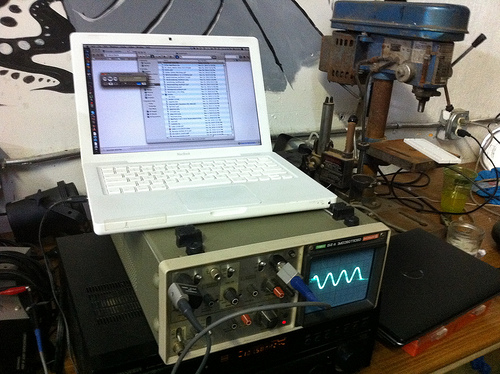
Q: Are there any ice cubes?
A: No, there are no ice cubes.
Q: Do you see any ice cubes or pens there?
A: No, there are no ice cubes or pens.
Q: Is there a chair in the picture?
A: No, there are no chairs.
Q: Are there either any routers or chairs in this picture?
A: No, there are no chairs or routers.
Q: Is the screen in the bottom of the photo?
A: Yes, the screen is in the bottom of the image.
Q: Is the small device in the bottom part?
A: Yes, the screen is in the bottom of the image.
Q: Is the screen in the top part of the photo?
A: No, the screen is in the bottom of the image.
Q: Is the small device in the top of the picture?
A: No, the screen is in the bottom of the image.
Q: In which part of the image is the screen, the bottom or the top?
A: The screen is in the bottom of the image.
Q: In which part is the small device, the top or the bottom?
A: The screen is in the bottom of the image.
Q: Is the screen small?
A: Yes, the screen is small.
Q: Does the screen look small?
A: Yes, the screen is small.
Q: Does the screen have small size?
A: Yes, the screen is small.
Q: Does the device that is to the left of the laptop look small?
A: Yes, the screen is small.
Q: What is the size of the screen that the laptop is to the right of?
A: The screen is small.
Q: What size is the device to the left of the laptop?
A: The screen is small.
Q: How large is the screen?
A: The screen is small.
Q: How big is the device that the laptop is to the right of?
A: The screen is small.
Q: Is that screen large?
A: No, the screen is small.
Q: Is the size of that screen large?
A: No, the screen is small.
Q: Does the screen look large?
A: No, the screen is small.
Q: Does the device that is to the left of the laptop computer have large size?
A: No, the screen is small.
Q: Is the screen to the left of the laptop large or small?
A: The screen is small.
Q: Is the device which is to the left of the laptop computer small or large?
A: The screen is small.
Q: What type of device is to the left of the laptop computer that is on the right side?
A: The device is a screen.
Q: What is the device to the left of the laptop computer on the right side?
A: The device is a screen.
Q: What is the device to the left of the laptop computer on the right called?
A: The device is a screen.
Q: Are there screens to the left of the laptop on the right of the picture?
A: Yes, there is a screen to the left of the laptop computer.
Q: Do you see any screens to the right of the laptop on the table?
A: No, the screen is to the left of the laptop.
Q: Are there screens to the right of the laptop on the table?
A: No, the screen is to the left of the laptop.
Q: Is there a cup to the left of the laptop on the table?
A: No, there is a screen to the left of the laptop.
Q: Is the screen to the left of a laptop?
A: Yes, the screen is to the left of a laptop.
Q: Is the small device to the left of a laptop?
A: Yes, the screen is to the left of a laptop.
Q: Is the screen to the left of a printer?
A: No, the screen is to the left of a laptop.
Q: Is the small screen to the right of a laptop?
A: No, the screen is to the left of a laptop.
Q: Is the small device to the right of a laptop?
A: No, the screen is to the left of a laptop.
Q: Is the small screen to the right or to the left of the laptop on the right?
A: The screen is to the left of the laptop computer.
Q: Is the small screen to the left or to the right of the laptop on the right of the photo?
A: The screen is to the left of the laptop computer.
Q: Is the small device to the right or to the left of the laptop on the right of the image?
A: The screen is to the left of the laptop computer.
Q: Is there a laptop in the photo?
A: Yes, there is a laptop.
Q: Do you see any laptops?
A: Yes, there is a laptop.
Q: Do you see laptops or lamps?
A: Yes, there is a laptop.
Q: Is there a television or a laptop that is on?
A: Yes, the laptop is on.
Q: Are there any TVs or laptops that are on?
A: Yes, the laptop is on.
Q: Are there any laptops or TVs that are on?
A: Yes, the laptop is on.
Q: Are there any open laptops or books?
A: Yes, there is an open laptop.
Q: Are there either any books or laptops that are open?
A: Yes, the laptop is open.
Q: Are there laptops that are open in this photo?
A: Yes, there is an open laptop.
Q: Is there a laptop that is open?
A: Yes, there is a laptop that is open.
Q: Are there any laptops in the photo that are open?
A: Yes, there is a laptop that is open.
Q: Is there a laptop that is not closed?
A: Yes, there is a open laptop.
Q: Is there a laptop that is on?
A: Yes, there is a laptop that is on.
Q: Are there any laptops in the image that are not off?
A: Yes, there is a laptop that is on.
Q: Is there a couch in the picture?
A: No, there are no couches.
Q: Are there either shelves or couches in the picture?
A: No, there are no couches or shelves.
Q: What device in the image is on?
A: The device is a laptop.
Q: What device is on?
A: The device is a laptop.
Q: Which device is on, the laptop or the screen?
A: The laptop is on.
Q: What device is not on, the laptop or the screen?
A: The screen is not on.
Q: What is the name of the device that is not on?
A: The device is a screen.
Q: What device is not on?
A: The device is a screen.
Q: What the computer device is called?
A: The device is a laptop.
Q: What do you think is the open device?
A: The device is a laptop.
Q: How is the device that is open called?
A: The device is a laptop.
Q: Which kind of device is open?
A: The device is a laptop.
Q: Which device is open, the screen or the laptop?
A: The laptop is open.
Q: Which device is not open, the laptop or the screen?
A: The screen is not open.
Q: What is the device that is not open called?
A: The device is a screen.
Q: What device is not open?
A: The device is a screen.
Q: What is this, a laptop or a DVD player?
A: This is a laptop.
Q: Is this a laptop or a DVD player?
A: This is a laptop.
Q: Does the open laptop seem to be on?
A: Yes, the laptop is on.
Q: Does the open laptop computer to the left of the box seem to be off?
A: No, the laptop is on.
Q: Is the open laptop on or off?
A: The laptop computer is on.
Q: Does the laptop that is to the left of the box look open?
A: Yes, the laptop is open.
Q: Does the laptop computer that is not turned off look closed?
A: No, the laptop is open.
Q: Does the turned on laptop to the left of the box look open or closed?
A: The laptop computer is open.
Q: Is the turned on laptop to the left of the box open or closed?
A: The laptop computer is open.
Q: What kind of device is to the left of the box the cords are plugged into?
A: The device is a laptop.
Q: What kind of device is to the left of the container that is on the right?
A: The device is a laptop.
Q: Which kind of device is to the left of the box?
A: The device is a laptop.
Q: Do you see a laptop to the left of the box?
A: Yes, there is a laptop to the left of the box.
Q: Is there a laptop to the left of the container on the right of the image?
A: Yes, there is a laptop to the left of the box.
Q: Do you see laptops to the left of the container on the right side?
A: Yes, there is a laptop to the left of the box.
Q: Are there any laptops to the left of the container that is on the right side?
A: Yes, there is a laptop to the left of the box.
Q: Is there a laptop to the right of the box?
A: No, the laptop is to the left of the box.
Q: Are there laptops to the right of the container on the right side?
A: No, the laptop is to the left of the box.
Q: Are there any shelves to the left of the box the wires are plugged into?
A: No, there is a laptop to the left of the box.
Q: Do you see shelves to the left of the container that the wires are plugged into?
A: No, there is a laptop to the left of the box.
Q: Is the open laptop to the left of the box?
A: Yes, the laptop computer is to the left of the box.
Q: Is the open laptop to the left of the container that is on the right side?
A: Yes, the laptop computer is to the left of the box.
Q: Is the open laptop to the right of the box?
A: No, the laptop is to the left of the box.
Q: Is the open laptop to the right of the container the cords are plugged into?
A: No, the laptop is to the left of the box.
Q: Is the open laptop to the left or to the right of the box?
A: The laptop is to the left of the box.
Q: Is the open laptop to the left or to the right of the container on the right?
A: The laptop is to the left of the box.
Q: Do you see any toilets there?
A: No, there are no toilets.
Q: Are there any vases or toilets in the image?
A: No, there are no toilets or vases.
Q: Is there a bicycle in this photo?
A: No, there are no bicycles.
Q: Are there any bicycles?
A: No, there are no bicycles.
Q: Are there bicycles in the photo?
A: No, there are no bicycles.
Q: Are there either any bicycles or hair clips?
A: No, there are no bicycles or hair clips.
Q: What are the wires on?
A: The wires are on the table.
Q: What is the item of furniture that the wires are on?
A: The piece of furniture is a table.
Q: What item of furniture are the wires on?
A: The wires are on the table.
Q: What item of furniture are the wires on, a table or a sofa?
A: The wires are on a table.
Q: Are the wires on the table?
A: Yes, the wires are on the table.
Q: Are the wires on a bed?
A: No, the wires are on the table.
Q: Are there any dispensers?
A: No, there are no dispensers.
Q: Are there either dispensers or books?
A: No, there are no dispensers or books.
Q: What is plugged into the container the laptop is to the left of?
A: The cords are plugged into the box.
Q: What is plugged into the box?
A: The cords are plugged into the box.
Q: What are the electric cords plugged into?
A: The wires are plugged into the box.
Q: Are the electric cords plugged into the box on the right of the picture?
A: Yes, the cords are plugged into the box.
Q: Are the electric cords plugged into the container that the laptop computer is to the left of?
A: Yes, the cords are plugged into the box.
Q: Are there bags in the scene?
A: No, there are no bags.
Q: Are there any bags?
A: No, there are no bags.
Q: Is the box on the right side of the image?
A: Yes, the box is on the right of the image.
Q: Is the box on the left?
A: No, the box is on the right of the image.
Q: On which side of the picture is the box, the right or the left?
A: The box is on the right of the image.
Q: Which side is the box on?
A: The box is on the right of the image.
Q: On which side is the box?
A: The box is on the right of the image.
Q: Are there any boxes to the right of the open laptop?
A: Yes, there is a box to the right of the laptop.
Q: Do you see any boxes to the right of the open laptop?
A: Yes, there is a box to the right of the laptop.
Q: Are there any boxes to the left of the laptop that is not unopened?
A: No, the box is to the right of the laptop.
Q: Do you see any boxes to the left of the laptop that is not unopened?
A: No, the box is to the right of the laptop.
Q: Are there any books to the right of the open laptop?
A: No, there is a box to the right of the laptop.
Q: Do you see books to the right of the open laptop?
A: No, there is a box to the right of the laptop.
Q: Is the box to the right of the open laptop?
A: Yes, the box is to the right of the laptop computer.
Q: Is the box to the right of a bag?
A: No, the box is to the right of the laptop computer.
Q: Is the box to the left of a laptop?
A: No, the box is to the right of a laptop.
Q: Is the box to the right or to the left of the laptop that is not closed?
A: The box is to the right of the laptop computer.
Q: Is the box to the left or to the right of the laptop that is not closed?
A: The box is to the right of the laptop computer.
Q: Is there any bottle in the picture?
A: No, there are no bottles.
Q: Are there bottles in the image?
A: No, there are no bottles.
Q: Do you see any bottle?
A: No, there are no bottles.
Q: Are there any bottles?
A: No, there are no bottles.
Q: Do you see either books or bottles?
A: No, there are no bottles or books.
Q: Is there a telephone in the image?
A: No, there are no phones.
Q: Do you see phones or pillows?
A: No, there are no phones or pillows.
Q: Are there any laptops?
A: Yes, there is a laptop.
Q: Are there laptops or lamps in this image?
A: Yes, there is a laptop.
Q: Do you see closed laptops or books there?
A: Yes, there is a closed laptop.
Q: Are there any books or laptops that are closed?
A: Yes, the laptop is closed.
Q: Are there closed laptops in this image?
A: Yes, there is a closed laptop.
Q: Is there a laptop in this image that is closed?
A: Yes, there is a laptop that is closed.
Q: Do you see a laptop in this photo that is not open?
A: Yes, there is an closed laptop.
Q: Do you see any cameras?
A: No, there are no cameras.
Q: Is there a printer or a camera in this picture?
A: No, there are no cameras or printers.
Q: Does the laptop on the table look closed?
A: Yes, the laptop is closed.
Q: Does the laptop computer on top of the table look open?
A: No, the laptop computer is closed.